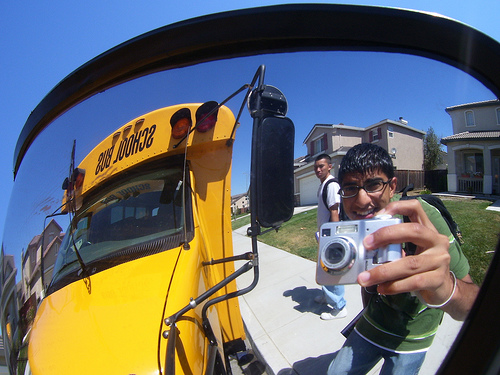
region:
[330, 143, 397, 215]
boy wearing glasses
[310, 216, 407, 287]
the camera is silver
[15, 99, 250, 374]
the bus is yellow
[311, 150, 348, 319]
bot wearing white shirt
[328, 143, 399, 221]
the boy is smiling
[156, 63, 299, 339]
side view mirror on bus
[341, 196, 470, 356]
the shirt is green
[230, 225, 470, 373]
boy standing on sidewalk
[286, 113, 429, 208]
a house with a garage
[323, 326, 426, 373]
the jeans are blue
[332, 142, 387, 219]
the head of a student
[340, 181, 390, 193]
the eyes of a student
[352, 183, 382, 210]
the nose of a student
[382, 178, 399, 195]
the ears of a student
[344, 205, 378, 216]
the teeth of a student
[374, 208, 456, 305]
the hand of a student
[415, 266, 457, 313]
the bracelet of a student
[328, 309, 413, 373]
the pants of a student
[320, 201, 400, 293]
a small and silver camera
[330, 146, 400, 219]
a guy wearing glasses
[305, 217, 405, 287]
a silver photo camera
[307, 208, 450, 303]
a hand holding a camera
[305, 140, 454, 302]
a guy holding a camera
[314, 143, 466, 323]
a guy holding a silver camera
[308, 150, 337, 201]
a guy wearing a white shirt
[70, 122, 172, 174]
the curved front of a school bus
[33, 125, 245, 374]
reflection of a yellow school bus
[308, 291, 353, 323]
white sneakers on the pavement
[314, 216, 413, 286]
Silver camera in hand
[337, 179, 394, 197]
Glasses with black rim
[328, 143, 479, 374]
Man wearing black backpack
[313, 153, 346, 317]
Man wearing black backpack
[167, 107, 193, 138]
Front headlight on school bus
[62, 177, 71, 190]
Front headlight on school bus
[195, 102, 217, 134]
Front headlight on school bus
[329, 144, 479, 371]
Man wearing green shirt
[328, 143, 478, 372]
Man wearing blue jeans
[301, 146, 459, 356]
a student with a camera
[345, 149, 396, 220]
the head of a student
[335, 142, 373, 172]
the hair of a student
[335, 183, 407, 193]
the glasses of a student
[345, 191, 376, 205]
the nose of a student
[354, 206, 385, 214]
the mouth of a student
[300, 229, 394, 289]
the camera of a student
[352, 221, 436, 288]
the fingers of a student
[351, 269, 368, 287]
the finger nail of a student